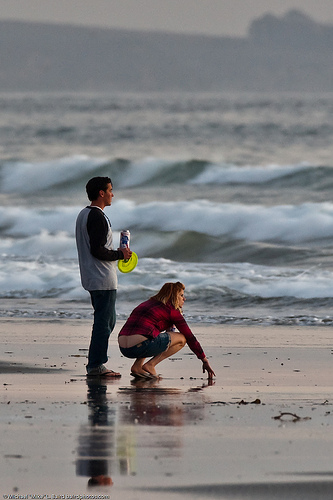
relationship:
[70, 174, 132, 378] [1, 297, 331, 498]
man on shore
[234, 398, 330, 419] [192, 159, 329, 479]
debris on shore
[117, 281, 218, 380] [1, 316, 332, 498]
woman crouching on sand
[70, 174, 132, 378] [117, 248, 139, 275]
man holding frisbee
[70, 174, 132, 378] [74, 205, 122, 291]
man wearing shirt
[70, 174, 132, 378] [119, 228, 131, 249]
man holding beverage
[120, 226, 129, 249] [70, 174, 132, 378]
beverage held by man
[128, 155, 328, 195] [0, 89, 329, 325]
waves of ocean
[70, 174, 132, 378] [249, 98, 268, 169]
man on ground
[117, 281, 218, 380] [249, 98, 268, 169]
woman on ground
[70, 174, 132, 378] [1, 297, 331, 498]
man standing on shore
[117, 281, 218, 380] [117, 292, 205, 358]
woman wearing shirt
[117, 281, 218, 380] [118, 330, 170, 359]
woman wearing shorts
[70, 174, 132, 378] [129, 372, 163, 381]
man wearing flipflops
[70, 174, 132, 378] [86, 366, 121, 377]
man wearing sandals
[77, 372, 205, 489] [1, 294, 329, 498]
reflection on sand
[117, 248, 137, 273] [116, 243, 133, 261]
frisbee in hand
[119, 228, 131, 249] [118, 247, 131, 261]
beverage in hand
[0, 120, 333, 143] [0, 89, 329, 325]
wave in ocean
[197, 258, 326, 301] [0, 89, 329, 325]
foam in ocean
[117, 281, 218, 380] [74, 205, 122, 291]
woman wearing shirt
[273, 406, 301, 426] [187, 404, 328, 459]
debris washed onto sand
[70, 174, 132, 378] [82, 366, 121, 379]
man wearing sandals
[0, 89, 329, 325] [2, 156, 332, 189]
ocean behind waves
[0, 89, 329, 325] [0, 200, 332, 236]
ocean behind waves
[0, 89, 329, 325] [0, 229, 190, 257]
ocean behind waves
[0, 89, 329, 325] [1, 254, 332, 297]
ocean behind waves